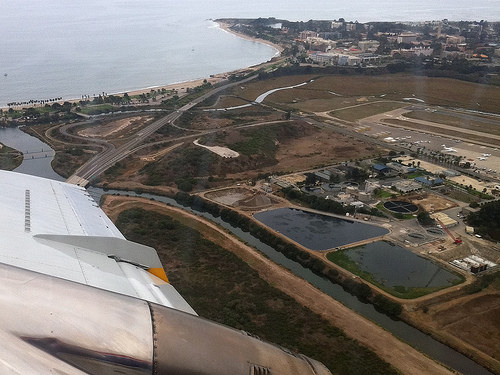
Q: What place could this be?
A: It is a field.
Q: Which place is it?
A: It is a field.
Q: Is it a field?
A: Yes, it is a field.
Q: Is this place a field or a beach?
A: It is a field.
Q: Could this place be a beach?
A: No, it is a field.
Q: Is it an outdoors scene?
A: Yes, it is outdoors.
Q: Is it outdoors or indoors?
A: It is outdoors.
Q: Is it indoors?
A: No, it is outdoors.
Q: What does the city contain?
A: The city contains highway.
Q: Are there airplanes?
A: Yes, there is an airplane.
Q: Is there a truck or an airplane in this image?
A: Yes, there is an airplane.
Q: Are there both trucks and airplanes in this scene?
A: No, there is an airplane but no trucks.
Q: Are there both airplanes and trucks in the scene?
A: No, there is an airplane but no trucks.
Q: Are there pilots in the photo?
A: No, there are no pilots.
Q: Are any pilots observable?
A: No, there are no pilots.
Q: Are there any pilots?
A: No, there are no pilots.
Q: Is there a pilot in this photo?
A: No, there are no pilots.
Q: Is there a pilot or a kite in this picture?
A: No, there are no pilots or kites.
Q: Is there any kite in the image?
A: No, there are no kites.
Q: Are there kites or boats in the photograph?
A: No, there are no kites or boats.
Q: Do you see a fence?
A: No, there are no fences.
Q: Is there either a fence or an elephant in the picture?
A: No, there are no fences or elephants.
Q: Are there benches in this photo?
A: No, there are no benches.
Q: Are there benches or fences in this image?
A: No, there are no benches or fences.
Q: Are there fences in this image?
A: No, there are no fences.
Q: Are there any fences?
A: No, there are no fences.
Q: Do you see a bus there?
A: No, there are no buses.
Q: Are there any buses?
A: No, there are no buses.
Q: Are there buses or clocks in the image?
A: No, there are no buses or clocks.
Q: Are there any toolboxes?
A: No, there are no toolboxes.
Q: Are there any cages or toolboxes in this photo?
A: No, there are no toolboxes or cages.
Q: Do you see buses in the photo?
A: No, there are no buses.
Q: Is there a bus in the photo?
A: No, there are no buses.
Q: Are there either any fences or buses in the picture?
A: No, there are no buses or fences.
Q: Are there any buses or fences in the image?
A: No, there are no buses or fences.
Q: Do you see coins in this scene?
A: No, there are no coins.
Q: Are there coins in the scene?
A: No, there are no coins.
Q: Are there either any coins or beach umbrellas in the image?
A: No, there are no coins or beach umbrellas.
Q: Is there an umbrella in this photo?
A: No, there are no umbrellas.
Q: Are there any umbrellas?
A: No, there are no umbrellas.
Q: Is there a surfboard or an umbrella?
A: No, there are no umbrellas or surfboards.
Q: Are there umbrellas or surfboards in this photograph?
A: No, there are no umbrellas or surfboards.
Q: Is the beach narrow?
A: Yes, the beach is narrow.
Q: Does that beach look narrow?
A: Yes, the beach is narrow.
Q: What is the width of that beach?
A: The beach is narrow.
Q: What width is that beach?
A: The beach is narrow.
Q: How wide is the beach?
A: The beach is narrow.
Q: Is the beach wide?
A: No, the beach is narrow.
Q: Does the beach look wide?
A: No, the beach is narrow.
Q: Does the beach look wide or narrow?
A: The beach is narrow.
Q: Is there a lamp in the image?
A: No, there are no lamps.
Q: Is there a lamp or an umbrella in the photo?
A: No, there are no lamps or umbrellas.